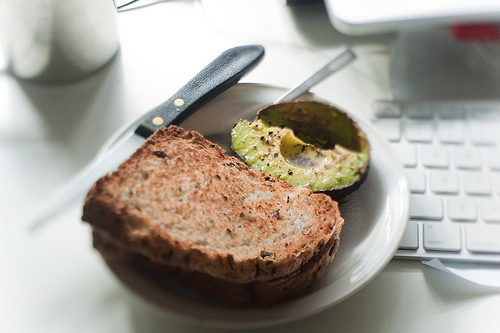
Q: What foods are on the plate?
A: Toast and avocado.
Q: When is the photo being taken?
A: Daytime.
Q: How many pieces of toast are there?
A: 2.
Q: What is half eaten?
A: Avocado.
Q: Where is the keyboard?
A: Next to the plate.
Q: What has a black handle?
A: A knife.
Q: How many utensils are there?
A: 2.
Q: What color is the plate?
A: White.